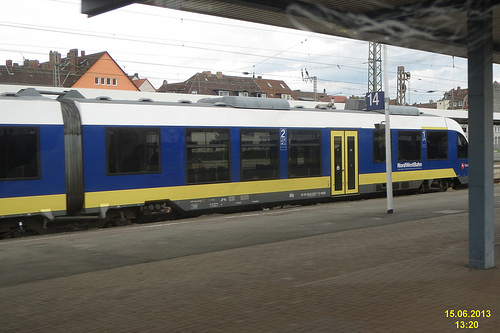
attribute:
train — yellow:
[5, 82, 498, 217]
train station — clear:
[1, 0, 499, 331]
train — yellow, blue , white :
[170, 100, 332, 203]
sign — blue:
[363, 89, 391, 116]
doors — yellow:
[328, 126, 359, 201]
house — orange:
[4, 46, 154, 94]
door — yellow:
[322, 126, 349, 198]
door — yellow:
[343, 116, 368, 206]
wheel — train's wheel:
[135, 202, 168, 212]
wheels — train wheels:
[0, 175, 463, 235]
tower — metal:
[391, 68, 445, 123]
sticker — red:
[455, 161, 470, 173]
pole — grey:
[454, 9, 499, 276]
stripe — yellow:
[0, 159, 458, 219]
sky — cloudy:
[4, 5, 495, 105]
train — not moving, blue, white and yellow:
[0, 77, 480, 248]